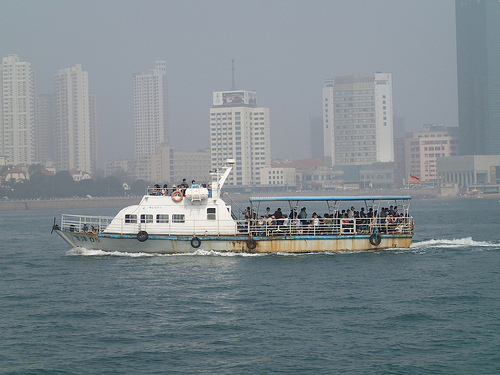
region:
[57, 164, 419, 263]
white boat skimming through water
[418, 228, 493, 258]
white wake boat is creating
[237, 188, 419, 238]
shelter with blue top on back of boat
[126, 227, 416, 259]
black floatation rings attached to side of boat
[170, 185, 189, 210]
orange floatation ring attached to side of cabin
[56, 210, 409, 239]
white railings on boat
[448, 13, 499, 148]
tall black building along shoreline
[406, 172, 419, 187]
red and yellow flag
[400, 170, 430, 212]
flag on back of boat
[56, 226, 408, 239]
blue strip running along edge of boat deck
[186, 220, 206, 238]
part of a boat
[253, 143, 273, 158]
part of a building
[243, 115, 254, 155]
edge of a building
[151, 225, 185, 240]
side of a boat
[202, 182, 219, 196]
top of a boat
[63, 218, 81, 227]
tip of a boat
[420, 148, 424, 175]
edge of a building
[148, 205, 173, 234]
tip of a boat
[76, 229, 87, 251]
side of a boat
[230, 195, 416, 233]
people standing on the boat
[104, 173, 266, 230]
front of boat is white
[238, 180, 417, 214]
shade covering over people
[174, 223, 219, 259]
black round object on boat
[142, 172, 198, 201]
people standing on top level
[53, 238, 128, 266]
waves underneath the boat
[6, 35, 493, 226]
city buildings seen in distance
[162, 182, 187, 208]
red round object on boat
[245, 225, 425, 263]
bottom of boat is dirty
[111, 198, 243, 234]
windows on side of boat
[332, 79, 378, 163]
Building with brownish face to the water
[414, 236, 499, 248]
Wave caused by boat propeller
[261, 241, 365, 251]
Rusty side of the boat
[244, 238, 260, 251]
Tire for cushioning side of the boat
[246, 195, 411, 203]
The blue sheltering roof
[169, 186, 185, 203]
A red life saving float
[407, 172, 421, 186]
A flag flying on the boat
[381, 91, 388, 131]
Windows on the side of a building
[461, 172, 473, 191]
Pillars supporting a building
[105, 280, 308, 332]
A body of water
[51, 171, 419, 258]
white boat traveling on waters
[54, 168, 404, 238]
people riding on the boat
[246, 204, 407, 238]
people riding on back boat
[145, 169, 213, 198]
people riding on top of boat's cabin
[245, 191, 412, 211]
blue shelter over top of people on back of boat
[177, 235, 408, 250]
rust spots on bottom of boat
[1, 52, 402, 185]
four tall buildings on shoreline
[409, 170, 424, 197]
flag flying on back of boat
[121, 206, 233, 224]
windows on boat's cabin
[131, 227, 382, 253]
black floatation devices hanging on side of boat